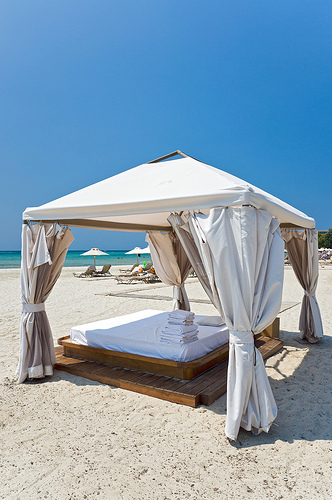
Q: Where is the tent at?
A: The beach.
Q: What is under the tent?
A: A mattress.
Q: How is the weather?
A: Blue sky and clear.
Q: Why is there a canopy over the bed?
A: For shade.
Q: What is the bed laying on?
A: Wooden platform.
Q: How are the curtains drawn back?
A: Tie-backs.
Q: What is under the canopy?
A: Bed.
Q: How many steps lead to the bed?
A: 1.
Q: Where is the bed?
A: Beach.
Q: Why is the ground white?
A: Sand.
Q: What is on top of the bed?
A: Towels and linens.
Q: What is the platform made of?
A: Wood.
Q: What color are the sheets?
A: White.